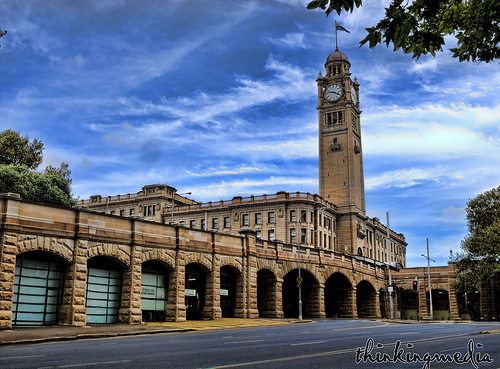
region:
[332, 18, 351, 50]
A flag on a tower.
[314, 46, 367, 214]
Tower on a building.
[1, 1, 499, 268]
A cloudy blue sky.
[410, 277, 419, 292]
A street light on red.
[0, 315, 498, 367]
An asphalt paved street.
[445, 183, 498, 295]
A tree on the sidewalk.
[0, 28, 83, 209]
A tree behind a building.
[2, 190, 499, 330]
A building with archways.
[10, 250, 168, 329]
Metal bars on doors.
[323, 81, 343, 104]
A clock on a tower.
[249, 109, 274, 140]
part of a cloud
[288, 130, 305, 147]
part of a xloud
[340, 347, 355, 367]
aprt of a line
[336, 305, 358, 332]
part f a oaf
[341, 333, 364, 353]
par of line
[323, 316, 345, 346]
part f a road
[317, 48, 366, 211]
a tall tower on the building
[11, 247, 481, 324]
a bunch of arch ways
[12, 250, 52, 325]
the shutter is down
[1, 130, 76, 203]
some fluffy green trees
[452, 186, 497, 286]
a tree near the building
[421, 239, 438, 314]
the pole is metal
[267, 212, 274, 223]
window on the building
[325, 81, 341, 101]
clock on the tower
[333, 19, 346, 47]
a flag is waving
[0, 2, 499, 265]
lots of clouds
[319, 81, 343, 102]
clock face on stone tower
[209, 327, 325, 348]
white lines painted on road pavement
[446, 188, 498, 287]
tree covered in green leaves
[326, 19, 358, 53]
flag on top of clock tower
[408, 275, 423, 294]
traffic signal indicating red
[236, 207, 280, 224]
row of windows on side of building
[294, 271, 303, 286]
yellow metal sign on pole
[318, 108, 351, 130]
windows on side of stone clock tower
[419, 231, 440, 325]
silver metal pole beside road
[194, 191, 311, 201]
brown guard railing on roof of building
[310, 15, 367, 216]
a tall brick clock tower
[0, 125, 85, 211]
a tall leafy green tree.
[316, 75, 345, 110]
a clock on a clock tower.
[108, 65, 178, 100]
a blue sky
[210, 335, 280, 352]
street is grey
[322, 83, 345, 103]
a clock on the building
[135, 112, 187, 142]
the clouds are white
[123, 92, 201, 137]
clouds in the sky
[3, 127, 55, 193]
the tree is green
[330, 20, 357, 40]
a flag on the building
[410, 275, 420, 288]
a light that is red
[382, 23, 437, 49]
the leaves are green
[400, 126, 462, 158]
a cloud that is white